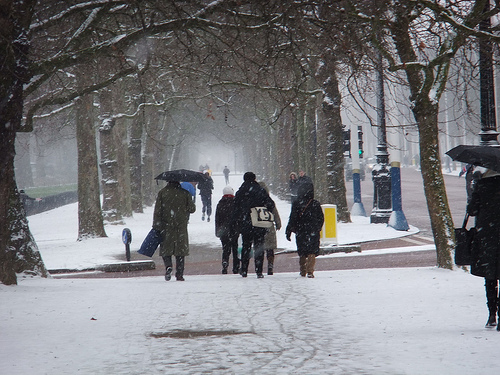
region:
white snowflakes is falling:
[8, 10, 498, 373]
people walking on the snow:
[37, 125, 499, 357]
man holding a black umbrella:
[134, 159, 215, 286]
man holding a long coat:
[134, 159, 204, 286]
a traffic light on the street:
[356, 127, 367, 163]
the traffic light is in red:
[351, 120, 366, 158]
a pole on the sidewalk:
[361, 4, 416, 238]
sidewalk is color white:
[0, 183, 481, 373]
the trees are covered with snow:
[0, 0, 499, 141]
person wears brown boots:
[285, 174, 334, 280]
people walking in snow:
[87, 75, 384, 327]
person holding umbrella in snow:
[137, 140, 209, 192]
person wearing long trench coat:
[145, 185, 200, 272]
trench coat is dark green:
[139, 176, 206, 269]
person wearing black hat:
[240, 165, 262, 187]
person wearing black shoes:
[159, 263, 187, 282]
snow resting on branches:
[18, 6, 236, 116]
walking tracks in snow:
[135, 270, 365, 370]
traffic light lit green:
[342, 122, 374, 174]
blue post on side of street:
[372, 143, 447, 255]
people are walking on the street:
[113, 127, 361, 272]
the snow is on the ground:
[62, 296, 352, 373]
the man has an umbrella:
[159, 137, 219, 269]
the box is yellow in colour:
[283, 175, 358, 246]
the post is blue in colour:
[384, 158, 407, 237]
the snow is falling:
[165, 118, 273, 153]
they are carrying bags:
[87, 170, 399, 277]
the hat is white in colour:
[211, 176, 238, 196]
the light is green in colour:
[348, 129, 371, 166]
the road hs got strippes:
[352, 219, 447, 274]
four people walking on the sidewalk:
[126, 160, 344, 284]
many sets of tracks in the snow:
[183, 344, 318, 374]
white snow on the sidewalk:
[379, 288, 454, 347]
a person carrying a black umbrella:
[438, 140, 499, 345]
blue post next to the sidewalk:
[383, 160, 412, 238]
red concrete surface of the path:
[352, 250, 407, 267]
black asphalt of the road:
[411, 179, 423, 216]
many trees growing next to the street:
[243, 80, 354, 214]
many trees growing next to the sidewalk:
[76, 98, 183, 215]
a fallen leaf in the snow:
[86, 308, 106, 333]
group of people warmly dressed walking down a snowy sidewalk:
[131, 163, 327, 294]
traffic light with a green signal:
[353, 123, 366, 158]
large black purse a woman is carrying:
[450, 212, 475, 268]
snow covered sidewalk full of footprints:
[119, 286, 361, 372]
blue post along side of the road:
[388, 162, 408, 234]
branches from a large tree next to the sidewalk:
[10, 7, 325, 103]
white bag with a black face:
[246, 199, 281, 226]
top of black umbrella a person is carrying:
[155, 165, 210, 185]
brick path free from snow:
[325, 245, 445, 270]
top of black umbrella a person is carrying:
[446, 137, 498, 178]